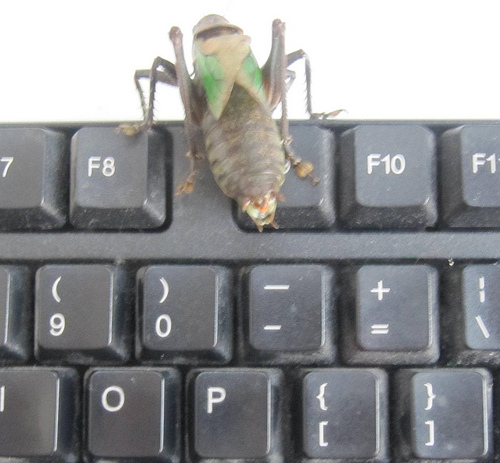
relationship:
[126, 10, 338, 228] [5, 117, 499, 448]
bug on keyboard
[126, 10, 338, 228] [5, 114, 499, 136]
bug at edge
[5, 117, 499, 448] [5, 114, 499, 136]
keyboard has edge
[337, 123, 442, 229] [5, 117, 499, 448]
f10 on keyboard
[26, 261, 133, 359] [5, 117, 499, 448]
key on keyboard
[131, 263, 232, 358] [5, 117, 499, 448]
key on keyboard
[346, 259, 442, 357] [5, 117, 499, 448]
key on keyboard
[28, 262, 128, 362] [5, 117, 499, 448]
9 on keyboard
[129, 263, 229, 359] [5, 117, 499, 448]
0 on keyboard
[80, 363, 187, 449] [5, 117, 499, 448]
o on keyboard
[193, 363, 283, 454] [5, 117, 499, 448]
p on keyboard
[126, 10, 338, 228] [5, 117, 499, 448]
grasshopper on keyboard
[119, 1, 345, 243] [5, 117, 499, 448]
grasshopper on keyboard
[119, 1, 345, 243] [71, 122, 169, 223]
grasshopper in between f8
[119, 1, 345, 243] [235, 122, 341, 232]
grasshopper in between f9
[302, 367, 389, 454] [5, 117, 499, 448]
key on keyboard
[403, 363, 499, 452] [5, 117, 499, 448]
key on keyboard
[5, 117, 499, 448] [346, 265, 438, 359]
keyboard has sign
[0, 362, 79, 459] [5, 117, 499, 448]
key on keyboard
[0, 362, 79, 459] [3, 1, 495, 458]
key in photo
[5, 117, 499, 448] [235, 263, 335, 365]
keyboard has key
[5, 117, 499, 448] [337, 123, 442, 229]
keyboard has key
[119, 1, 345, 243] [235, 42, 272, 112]
grasshopper with wing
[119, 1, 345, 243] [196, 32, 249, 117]
grasshopper with wing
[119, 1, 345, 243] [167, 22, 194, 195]
grasshopper has leg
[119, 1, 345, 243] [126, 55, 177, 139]
grasshopper has leg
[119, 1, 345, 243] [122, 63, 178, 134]
grasshopper has leg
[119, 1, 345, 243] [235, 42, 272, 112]
grasshopper has wing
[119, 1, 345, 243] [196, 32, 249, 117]
grasshopper has wing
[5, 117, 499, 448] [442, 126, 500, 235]
keyboard has key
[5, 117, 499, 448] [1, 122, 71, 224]
keyboard has key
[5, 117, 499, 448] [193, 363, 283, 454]
keyboard has key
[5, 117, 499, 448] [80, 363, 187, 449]
keyboard has key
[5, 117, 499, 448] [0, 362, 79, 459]
keyboard has key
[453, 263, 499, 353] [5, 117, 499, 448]
symbol on keyboard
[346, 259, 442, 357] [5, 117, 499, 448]
symbol on keyboard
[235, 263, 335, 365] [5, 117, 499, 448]
symbol on keyboard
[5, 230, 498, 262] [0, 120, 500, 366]
dust in between keys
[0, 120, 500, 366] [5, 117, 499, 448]
keys on keyboard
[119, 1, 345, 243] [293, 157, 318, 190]
grasshopper has foot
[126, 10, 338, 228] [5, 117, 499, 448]
guest on keyboard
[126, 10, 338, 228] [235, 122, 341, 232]
bug on key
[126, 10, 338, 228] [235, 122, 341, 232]
bug on f9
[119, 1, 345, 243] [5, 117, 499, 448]
grasshopper crawling on keyboard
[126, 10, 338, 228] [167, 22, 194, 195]
bug has leg